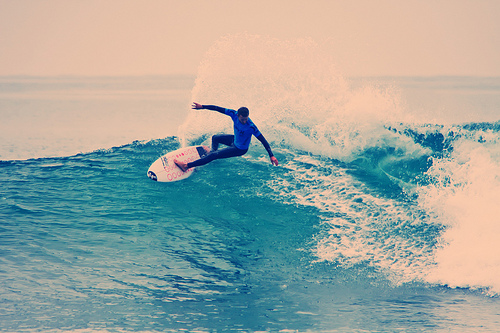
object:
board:
[146, 143, 213, 182]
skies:
[1, 1, 498, 76]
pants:
[181, 131, 248, 168]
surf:
[324, 82, 485, 275]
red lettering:
[167, 173, 173, 181]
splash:
[176, 47, 496, 293]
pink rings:
[164, 148, 200, 180]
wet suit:
[186, 104, 272, 168]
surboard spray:
[176, 129, 218, 151]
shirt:
[223, 107, 262, 150]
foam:
[332, 165, 428, 281]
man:
[172, 101, 279, 172]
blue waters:
[0, 0, 499, 332]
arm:
[250, 124, 277, 156]